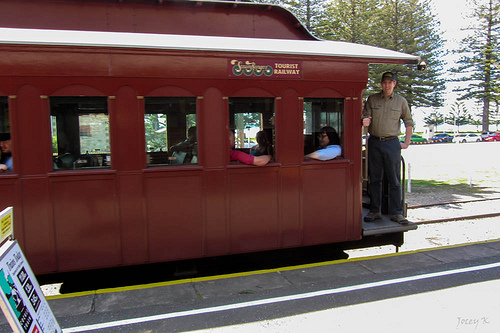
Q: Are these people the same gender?
A: No, they are both male and female.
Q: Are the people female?
A: No, they are both male and female.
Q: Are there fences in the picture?
A: No, there are no fences.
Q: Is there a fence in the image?
A: No, there are no fences.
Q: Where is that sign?
A: The sign is on the sidewalk.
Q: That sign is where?
A: The sign is on the sidewalk.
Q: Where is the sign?
A: The sign is on the sidewalk.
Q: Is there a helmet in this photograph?
A: No, there are no helmets.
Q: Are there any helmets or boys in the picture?
A: No, there are no helmets or boys.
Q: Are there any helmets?
A: No, there are no helmets.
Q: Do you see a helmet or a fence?
A: No, there are no helmets or fences.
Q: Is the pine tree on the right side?
A: Yes, the pine tree is on the right of the image.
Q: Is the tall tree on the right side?
A: Yes, the pine tree is on the right of the image.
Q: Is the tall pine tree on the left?
A: No, the pine tree is on the right of the image.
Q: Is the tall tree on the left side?
A: No, the pine tree is on the right of the image.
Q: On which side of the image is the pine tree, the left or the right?
A: The pine tree is on the right of the image.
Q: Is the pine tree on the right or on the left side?
A: The pine tree is on the right of the image.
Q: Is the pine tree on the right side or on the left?
A: The pine tree is on the right of the image.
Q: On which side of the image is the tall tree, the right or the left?
A: The pine tree is on the right of the image.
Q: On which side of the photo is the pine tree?
A: The pine tree is on the right of the image.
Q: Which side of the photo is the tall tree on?
A: The pine tree is on the right of the image.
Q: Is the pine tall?
A: Yes, the pine is tall.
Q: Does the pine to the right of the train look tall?
A: Yes, the pine tree is tall.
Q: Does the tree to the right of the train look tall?
A: Yes, the pine tree is tall.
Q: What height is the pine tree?
A: The pine tree is tall.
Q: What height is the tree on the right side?
A: The pine tree is tall.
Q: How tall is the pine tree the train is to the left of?
A: The pine tree is tall.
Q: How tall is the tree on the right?
A: The pine tree is tall.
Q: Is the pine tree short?
A: No, the pine tree is tall.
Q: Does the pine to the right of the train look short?
A: No, the pine is tall.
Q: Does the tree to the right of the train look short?
A: No, the pine is tall.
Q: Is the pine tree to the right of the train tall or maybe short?
A: The pine tree is tall.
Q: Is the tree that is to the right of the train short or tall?
A: The pine tree is tall.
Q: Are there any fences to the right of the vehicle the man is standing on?
A: No, there is a pine tree to the right of the train.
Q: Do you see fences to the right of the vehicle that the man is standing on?
A: No, there is a pine tree to the right of the train.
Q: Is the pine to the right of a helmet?
A: No, the pine is to the right of the train.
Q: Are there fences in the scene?
A: No, there are no fences.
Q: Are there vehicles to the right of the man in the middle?
A: Yes, there are vehicles to the right of the man.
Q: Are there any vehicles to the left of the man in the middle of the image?
A: No, the vehicles are to the right of the man.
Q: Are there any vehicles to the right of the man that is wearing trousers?
A: Yes, there are vehicles to the right of the man.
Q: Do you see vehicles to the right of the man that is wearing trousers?
A: Yes, there are vehicles to the right of the man.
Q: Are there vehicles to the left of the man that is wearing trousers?
A: No, the vehicles are to the right of the man.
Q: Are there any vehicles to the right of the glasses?
A: Yes, there are vehicles to the right of the glasses.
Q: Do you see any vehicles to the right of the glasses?
A: Yes, there are vehicles to the right of the glasses.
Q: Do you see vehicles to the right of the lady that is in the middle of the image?
A: Yes, there are vehicles to the right of the lady.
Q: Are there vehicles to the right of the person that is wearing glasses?
A: Yes, there are vehicles to the right of the lady.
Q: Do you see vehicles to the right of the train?
A: Yes, there are vehicles to the right of the train.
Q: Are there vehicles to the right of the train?
A: Yes, there are vehicles to the right of the train.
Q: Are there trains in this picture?
A: Yes, there is a train.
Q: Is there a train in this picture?
A: Yes, there is a train.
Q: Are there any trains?
A: Yes, there is a train.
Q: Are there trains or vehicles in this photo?
A: Yes, there is a train.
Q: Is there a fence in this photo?
A: No, there are no fences.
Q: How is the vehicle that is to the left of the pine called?
A: The vehicle is a train.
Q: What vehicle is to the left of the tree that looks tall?
A: The vehicle is a train.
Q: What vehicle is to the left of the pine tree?
A: The vehicle is a train.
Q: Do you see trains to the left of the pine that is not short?
A: Yes, there is a train to the left of the pine.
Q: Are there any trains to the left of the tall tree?
A: Yes, there is a train to the left of the pine.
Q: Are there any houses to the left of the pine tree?
A: No, there is a train to the left of the pine tree.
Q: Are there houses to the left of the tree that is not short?
A: No, there is a train to the left of the pine tree.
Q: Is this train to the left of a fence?
A: No, the train is to the left of a pine tree.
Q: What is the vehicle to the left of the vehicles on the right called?
A: The vehicle is a train.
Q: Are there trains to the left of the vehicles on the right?
A: Yes, there is a train to the left of the vehicles.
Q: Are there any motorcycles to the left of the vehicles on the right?
A: No, there is a train to the left of the vehicles.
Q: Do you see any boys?
A: No, there are no boys.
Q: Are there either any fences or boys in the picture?
A: No, there are no boys or fences.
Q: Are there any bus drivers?
A: No, there are no bus drivers.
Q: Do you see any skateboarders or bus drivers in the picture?
A: No, there are no bus drivers or skateboarders.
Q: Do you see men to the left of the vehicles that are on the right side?
A: Yes, there is a man to the left of the vehicles.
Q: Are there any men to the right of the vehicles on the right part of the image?
A: No, the man is to the left of the vehicles.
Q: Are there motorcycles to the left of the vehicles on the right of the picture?
A: No, there is a man to the left of the vehicles.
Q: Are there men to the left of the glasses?
A: Yes, there is a man to the left of the glasses.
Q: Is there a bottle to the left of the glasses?
A: No, there is a man to the left of the glasses.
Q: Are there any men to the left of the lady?
A: Yes, there is a man to the left of the lady.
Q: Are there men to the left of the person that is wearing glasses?
A: Yes, there is a man to the left of the lady.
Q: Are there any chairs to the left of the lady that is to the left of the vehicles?
A: No, there is a man to the left of the lady.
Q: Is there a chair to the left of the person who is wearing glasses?
A: No, there is a man to the left of the lady.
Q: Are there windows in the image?
A: Yes, there is a window.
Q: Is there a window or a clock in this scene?
A: Yes, there is a window.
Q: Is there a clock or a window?
A: Yes, there is a window.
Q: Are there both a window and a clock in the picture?
A: No, there is a window but no clocks.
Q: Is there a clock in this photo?
A: No, there are no clocks.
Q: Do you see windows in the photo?
A: Yes, there is a window.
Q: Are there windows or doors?
A: Yes, there is a window.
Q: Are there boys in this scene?
A: No, there are no boys.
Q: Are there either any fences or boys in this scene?
A: No, there are no boys or fences.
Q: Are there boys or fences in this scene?
A: No, there are no boys or fences.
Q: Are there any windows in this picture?
A: Yes, there is a window.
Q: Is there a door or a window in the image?
A: Yes, there is a window.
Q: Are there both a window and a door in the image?
A: No, there is a window but no doors.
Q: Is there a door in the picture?
A: No, there are no doors.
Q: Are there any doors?
A: No, there are no doors.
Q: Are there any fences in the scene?
A: No, there are no fences.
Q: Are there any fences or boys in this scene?
A: No, there are no fences or boys.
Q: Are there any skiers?
A: No, there are no skiers.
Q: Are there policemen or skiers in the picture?
A: No, there are no skiers or policemen.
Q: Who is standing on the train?
A: The man is standing on the train.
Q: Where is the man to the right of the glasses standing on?
A: The man is standing on the train.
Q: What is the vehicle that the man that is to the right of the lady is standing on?
A: The vehicle is a train.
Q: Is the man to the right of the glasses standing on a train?
A: Yes, the man is standing on a train.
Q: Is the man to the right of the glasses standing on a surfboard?
A: No, the man is standing on a train.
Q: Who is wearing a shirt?
A: The man is wearing a shirt.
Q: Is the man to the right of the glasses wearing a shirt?
A: Yes, the man is wearing a shirt.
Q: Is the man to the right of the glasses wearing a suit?
A: No, the man is wearing a shirt.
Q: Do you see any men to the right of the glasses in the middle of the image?
A: Yes, there is a man to the right of the glasses.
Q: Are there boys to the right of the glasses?
A: No, there is a man to the right of the glasses.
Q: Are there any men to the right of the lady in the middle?
A: Yes, there is a man to the right of the lady.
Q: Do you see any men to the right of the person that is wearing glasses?
A: Yes, there is a man to the right of the lady.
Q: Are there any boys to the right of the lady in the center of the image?
A: No, there is a man to the right of the lady.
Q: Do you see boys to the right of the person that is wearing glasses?
A: No, there is a man to the right of the lady.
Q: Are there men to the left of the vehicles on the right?
A: Yes, there is a man to the left of the vehicles.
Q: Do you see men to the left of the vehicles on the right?
A: Yes, there is a man to the left of the vehicles.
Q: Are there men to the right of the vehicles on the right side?
A: No, the man is to the left of the vehicles.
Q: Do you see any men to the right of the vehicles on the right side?
A: No, the man is to the left of the vehicles.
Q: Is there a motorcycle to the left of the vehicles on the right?
A: No, there is a man to the left of the vehicles.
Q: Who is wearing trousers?
A: The man is wearing trousers.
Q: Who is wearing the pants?
A: The man is wearing trousers.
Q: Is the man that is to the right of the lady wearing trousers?
A: Yes, the man is wearing trousers.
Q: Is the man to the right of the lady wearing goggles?
A: No, the man is wearing trousers.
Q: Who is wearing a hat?
A: The man is wearing a hat.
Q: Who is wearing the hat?
A: The man is wearing a hat.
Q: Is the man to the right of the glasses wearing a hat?
A: Yes, the man is wearing a hat.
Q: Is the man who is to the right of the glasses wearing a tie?
A: No, the man is wearing a hat.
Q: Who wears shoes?
A: The man wears shoes.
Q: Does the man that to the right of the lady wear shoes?
A: Yes, the man wears shoes.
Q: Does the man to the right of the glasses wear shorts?
A: No, the man wears shoes.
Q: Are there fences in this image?
A: No, there are no fences.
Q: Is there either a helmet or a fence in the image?
A: No, there are no fences or helmets.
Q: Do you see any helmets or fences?
A: No, there are no fences or helmets.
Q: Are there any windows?
A: Yes, there is a window.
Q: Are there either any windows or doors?
A: Yes, there is a window.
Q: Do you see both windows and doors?
A: No, there is a window but no doors.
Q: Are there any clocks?
A: No, there are no clocks.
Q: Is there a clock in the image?
A: No, there are no clocks.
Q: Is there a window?
A: Yes, there is a window.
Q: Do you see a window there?
A: Yes, there is a window.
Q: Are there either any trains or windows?
A: Yes, there is a window.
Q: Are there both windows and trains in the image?
A: Yes, there are both a window and a train.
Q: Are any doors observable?
A: No, there are no doors.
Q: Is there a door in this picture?
A: No, there are no doors.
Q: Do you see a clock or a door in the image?
A: No, there are no doors or clocks.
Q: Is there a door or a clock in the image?
A: No, there are no doors or clocks.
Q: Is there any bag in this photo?
A: No, there are no bags.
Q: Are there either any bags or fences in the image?
A: No, there are no bags or fences.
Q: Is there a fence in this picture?
A: No, there are no fences.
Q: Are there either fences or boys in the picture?
A: No, there are no fences or boys.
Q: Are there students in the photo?
A: No, there are no students.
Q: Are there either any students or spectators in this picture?
A: No, there are no students or spectators.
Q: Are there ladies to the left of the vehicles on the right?
A: Yes, there is a lady to the left of the vehicles.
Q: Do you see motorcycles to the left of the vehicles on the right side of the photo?
A: No, there is a lady to the left of the vehicles.